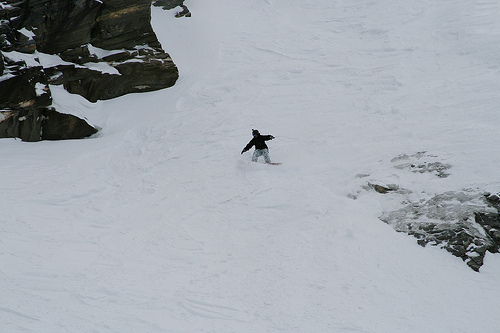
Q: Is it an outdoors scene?
A: Yes, it is outdoors.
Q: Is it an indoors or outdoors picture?
A: It is outdoors.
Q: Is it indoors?
A: No, it is outdoors.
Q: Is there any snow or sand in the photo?
A: Yes, there is snow.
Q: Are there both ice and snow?
A: Yes, there are both snow and ice.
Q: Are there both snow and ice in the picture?
A: Yes, there are both snow and ice.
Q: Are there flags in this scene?
A: No, there are no flags.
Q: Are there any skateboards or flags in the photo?
A: No, there are no flags or skateboards.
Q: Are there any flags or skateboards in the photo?
A: No, there are no flags or skateboards.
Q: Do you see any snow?
A: Yes, there is snow.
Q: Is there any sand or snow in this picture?
A: Yes, there is snow.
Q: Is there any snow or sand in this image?
A: Yes, there is snow.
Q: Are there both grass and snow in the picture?
A: No, there is snow but no grass.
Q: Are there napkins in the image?
A: No, there are no napkins.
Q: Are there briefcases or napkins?
A: No, there are no napkins or briefcases.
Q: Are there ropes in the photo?
A: No, there are no ropes.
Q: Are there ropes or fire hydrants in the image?
A: No, there are no ropes or fire hydrants.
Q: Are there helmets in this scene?
A: No, there are no helmets.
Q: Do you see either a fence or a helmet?
A: No, there are no helmets or fences.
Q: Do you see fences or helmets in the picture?
A: No, there are no helmets or fences.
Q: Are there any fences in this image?
A: No, there are no fences.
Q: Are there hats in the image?
A: Yes, there is a hat.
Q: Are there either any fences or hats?
A: Yes, there is a hat.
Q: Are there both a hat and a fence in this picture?
A: No, there is a hat but no fences.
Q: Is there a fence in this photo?
A: No, there are no fences.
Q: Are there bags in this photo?
A: No, there are no bags.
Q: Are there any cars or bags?
A: No, there are no bags or cars.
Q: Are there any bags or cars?
A: No, there are no bags or cars.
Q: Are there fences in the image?
A: No, there are no fences.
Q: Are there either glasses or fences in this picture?
A: No, there are no fences or glasses.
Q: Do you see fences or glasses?
A: No, there are no fences or glasses.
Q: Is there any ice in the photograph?
A: Yes, there is ice.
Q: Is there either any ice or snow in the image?
A: Yes, there is ice.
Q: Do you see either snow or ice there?
A: Yes, there is ice.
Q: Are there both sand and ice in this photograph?
A: No, there is ice but no sand.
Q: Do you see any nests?
A: No, there are no nests.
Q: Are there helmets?
A: No, there are no helmets.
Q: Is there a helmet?
A: No, there are no helmets.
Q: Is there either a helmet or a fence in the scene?
A: No, there are no helmets or fences.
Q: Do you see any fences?
A: No, there are no fences.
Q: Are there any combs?
A: No, there are no combs.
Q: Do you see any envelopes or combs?
A: No, there are no combs or envelopes.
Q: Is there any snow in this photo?
A: Yes, there is snow.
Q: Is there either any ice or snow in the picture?
A: Yes, there is snow.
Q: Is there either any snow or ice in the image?
A: Yes, there is snow.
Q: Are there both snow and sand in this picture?
A: No, there is snow but no sand.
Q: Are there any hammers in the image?
A: No, there are no hammers.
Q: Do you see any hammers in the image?
A: No, there are no hammers.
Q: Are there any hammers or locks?
A: No, there are no hammers or locks.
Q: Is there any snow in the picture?
A: Yes, there is snow.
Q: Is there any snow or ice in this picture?
A: Yes, there is snow.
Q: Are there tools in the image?
A: No, there are no tools.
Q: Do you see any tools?
A: No, there are no tools.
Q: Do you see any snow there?
A: Yes, there is snow.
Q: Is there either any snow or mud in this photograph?
A: Yes, there is snow.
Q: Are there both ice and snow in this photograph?
A: Yes, there are both snow and ice.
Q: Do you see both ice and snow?
A: Yes, there are both snow and ice.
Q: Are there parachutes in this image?
A: No, there are no parachutes.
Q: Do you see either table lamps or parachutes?
A: No, there are no parachutes or table lamps.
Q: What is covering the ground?
A: The snow is covering the ground.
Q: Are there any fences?
A: No, there are no fences.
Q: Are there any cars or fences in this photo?
A: No, there are no fences or cars.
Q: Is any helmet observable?
A: No, there are no helmets.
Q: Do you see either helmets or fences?
A: No, there are no helmets or fences.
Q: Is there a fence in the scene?
A: No, there are no fences.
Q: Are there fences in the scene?
A: No, there are no fences.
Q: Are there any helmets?
A: No, there are no helmets.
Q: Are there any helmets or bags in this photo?
A: No, there are no helmets or bags.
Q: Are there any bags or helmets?
A: No, there are no helmets or bags.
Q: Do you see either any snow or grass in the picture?
A: Yes, there is snow.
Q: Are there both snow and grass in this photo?
A: No, there is snow but no grass.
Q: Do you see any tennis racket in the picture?
A: No, there are no rackets.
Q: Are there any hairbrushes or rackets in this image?
A: No, there are no rackets or hairbrushes.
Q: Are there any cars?
A: No, there are no cars.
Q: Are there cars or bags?
A: No, there are no cars or bags.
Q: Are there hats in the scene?
A: Yes, there is a hat.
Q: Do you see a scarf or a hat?
A: Yes, there is a hat.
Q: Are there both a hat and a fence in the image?
A: No, there is a hat but no fences.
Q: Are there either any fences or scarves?
A: No, there are no fences or scarves.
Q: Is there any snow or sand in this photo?
A: Yes, there is snow.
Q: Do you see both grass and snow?
A: No, there is snow but no grass.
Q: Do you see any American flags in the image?
A: No, there are no American flags.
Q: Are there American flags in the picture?
A: No, there are no American flags.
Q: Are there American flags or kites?
A: No, there are no American flags or kites.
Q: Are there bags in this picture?
A: No, there are no bags.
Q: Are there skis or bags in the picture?
A: No, there are no bags or skis.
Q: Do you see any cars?
A: No, there are no cars.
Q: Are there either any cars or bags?
A: No, there are no cars or bags.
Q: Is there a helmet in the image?
A: No, there are no helmets.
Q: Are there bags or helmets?
A: No, there are no helmets or bags.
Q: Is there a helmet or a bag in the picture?
A: No, there are no helmets or bags.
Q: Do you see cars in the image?
A: No, there are no cars.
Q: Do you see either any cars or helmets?
A: No, there are no cars or helmets.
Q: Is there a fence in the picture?
A: No, there are no fences.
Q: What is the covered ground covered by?
A: The ground is covered by the snow.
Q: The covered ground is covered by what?
A: The ground is covered by the snow.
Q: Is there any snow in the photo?
A: Yes, there is snow.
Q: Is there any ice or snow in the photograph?
A: Yes, there is snow.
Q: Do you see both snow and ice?
A: Yes, there are both snow and ice.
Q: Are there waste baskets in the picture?
A: No, there are no waste baskets.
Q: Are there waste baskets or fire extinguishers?
A: No, there are no waste baskets or fire extinguishers.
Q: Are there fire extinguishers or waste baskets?
A: No, there are no waste baskets or fire extinguishers.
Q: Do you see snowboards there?
A: Yes, there is a snowboard.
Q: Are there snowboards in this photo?
A: Yes, there is a snowboard.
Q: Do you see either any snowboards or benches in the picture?
A: Yes, there is a snowboard.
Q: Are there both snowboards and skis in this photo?
A: No, there is a snowboard but no skis.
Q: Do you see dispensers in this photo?
A: No, there are no dispensers.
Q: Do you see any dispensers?
A: No, there are no dispensers.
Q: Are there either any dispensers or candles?
A: No, there are no dispensers or candles.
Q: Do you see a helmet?
A: No, there are no helmets.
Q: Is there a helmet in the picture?
A: No, there are no helmets.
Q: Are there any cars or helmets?
A: No, there are no helmets or cars.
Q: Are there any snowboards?
A: Yes, there is a snowboard.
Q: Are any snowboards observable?
A: Yes, there is a snowboard.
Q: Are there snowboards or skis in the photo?
A: Yes, there is a snowboard.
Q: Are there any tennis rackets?
A: No, there are no tennis rackets.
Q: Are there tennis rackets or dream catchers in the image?
A: No, there are no tennis rackets or dream catchers.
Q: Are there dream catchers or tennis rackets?
A: No, there are no tennis rackets or dream catchers.